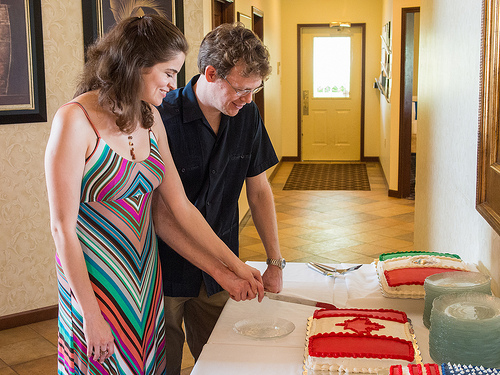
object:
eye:
[164, 72, 173, 78]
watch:
[265, 258, 286, 271]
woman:
[42, 4, 263, 375]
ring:
[101, 350, 109, 354]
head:
[197, 22, 273, 117]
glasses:
[221, 74, 264, 97]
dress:
[56, 101, 167, 375]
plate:
[232, 271, 500, 370]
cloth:
[188, 260, 437, 375]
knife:
[257, 291, 336, 310]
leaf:
[335, 317, 385, 335]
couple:
[44, 4, 286, 375]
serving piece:
[258, 284, 336, 321]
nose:
[168, 74, 177, 90]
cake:
[374, 251, 470, 300]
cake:
[302, 307, 423, 374]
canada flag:
[308, 308, 415, 362]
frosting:
[379, 250, 466, 287]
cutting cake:
[225, 266, 382, 332]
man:
[152, 23, 286, 375]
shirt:
[153, 73, 281, 299]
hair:
[71, 0, 189, 135]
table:
[188, 260, 495, 375]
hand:
[216, 272, 264, 303]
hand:
[231, 264, 263, 294]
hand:
[262, 265, 284, 294]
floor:
[0, 191, 500, 374]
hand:
[83, 318, 114, 363]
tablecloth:
[187, 260, 491, 374]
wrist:
[268, 261, 283, 271]